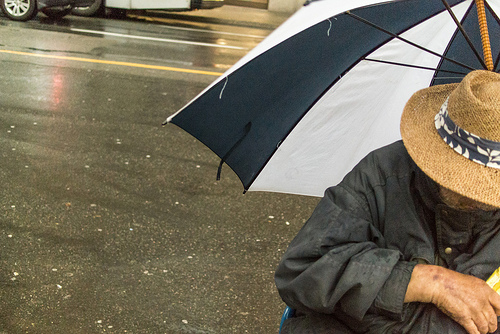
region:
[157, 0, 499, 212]
blue and white umbrella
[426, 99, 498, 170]
blue and white ribbon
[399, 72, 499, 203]
ribbon around the hat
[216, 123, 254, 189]
black strap hanging off the umbrella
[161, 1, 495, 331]
person under the umbrella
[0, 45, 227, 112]
yellow line on the road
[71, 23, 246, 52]
white line on the ground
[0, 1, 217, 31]
vehicle on the road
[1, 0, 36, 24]
silver rim on a black tire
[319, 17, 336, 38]
thin white string hanging down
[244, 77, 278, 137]
Blue section on umbrella.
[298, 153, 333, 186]
White section of the umbrella.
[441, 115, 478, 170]
Blue and white band on hat.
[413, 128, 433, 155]
Person wearing hat on head.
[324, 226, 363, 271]
Person wearing gray coat.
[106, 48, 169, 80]
Yellow line marking road.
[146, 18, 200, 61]
White line marking road.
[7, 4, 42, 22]
Black wheel on vehicle.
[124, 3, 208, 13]
White vehicle on road.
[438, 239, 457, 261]
Gold snap on person's coat.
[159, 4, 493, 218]
umbrella is blue and white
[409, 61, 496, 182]
hat has a strap around it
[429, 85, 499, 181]
strap around house is blue and white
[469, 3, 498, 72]
wooden post on the umbrella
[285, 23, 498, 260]
umbrella over the person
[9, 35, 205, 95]
yellow line in the road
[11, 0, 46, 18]
tire on a vehicle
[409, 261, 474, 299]
sores on the person's hand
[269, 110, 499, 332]
jacket is black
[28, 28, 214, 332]
rain on the road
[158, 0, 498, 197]
underside of black and white umbrella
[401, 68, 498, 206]
straw hat with gray and white floral band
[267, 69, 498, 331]
man in hat and black jacket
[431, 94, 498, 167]
gray and white floral hat band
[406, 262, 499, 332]
tanned man's hand with age spots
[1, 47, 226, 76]
painted yellow street line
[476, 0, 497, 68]
tan wooden umbrella handle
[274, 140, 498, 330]
weathered black rain jacket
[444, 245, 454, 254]
shiny round metal button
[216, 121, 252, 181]
black fabric umbrella strap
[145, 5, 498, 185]
a blue and white umbrella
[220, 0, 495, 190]
the underside of an umbrella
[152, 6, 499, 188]
a blue and white striped umbrella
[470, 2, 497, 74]
part of the handle of an umbrella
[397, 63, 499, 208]
a straw hat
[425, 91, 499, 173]
fabric on a straw hat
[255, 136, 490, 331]
a person wearing a jacket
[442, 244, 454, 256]
a snap on a jacket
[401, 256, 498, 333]
a hand on a jacket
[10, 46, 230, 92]
a yellow line in the road